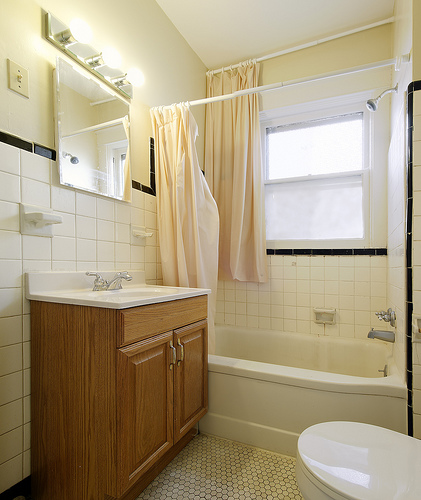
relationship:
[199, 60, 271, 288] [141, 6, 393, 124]
curtain on rod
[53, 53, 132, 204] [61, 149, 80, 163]
mirror reflecting shower head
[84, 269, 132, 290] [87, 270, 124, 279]
faucet with handles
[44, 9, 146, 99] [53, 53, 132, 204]
lights in a row above mirror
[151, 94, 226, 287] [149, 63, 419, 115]
curtain on rod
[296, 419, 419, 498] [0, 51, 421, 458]
lid in bathroom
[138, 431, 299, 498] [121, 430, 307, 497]
hexagonal tiles on floor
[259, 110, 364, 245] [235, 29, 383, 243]
window on wall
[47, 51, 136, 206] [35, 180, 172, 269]
mirror mounted on wall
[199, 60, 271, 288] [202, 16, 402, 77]
curtain on rod